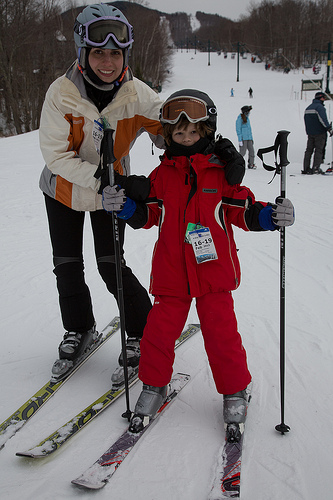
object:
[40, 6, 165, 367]
instructor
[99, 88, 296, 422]
child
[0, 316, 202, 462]
skis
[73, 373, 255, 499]
skis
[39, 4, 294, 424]
people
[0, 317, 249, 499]
skis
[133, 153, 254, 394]
snowsuit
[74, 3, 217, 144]
gear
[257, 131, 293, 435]
pole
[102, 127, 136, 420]
pole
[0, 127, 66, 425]
snow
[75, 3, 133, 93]
helmet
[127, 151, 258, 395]
red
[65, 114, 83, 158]
orange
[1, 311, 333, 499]
snow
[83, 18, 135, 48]
goggles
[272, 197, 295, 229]
glove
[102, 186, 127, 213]
glove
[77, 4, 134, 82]
head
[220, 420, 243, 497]
ski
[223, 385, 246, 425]
foot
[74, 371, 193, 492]
ski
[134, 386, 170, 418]
foot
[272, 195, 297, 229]
hand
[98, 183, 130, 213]
hand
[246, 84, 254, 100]
skier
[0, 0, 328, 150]
background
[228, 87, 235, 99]
skier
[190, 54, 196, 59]
skier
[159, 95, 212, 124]
goggles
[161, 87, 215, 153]
head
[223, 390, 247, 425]
boot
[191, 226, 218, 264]
tag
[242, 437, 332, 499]
track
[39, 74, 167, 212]
jacket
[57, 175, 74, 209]
accent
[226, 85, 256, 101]
people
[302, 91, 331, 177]
man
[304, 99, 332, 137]
coat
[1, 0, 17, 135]
tree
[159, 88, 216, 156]
helmet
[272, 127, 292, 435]
stick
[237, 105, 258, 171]
lady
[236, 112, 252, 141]
jacket